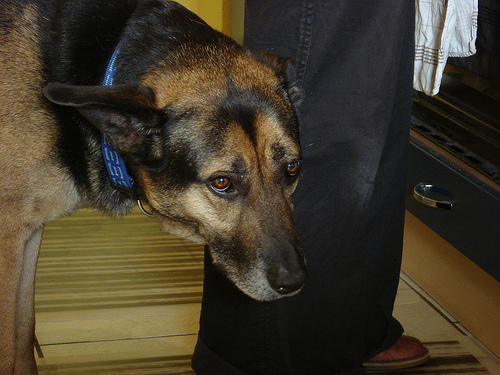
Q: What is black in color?
A: Pant legs of man.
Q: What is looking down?
A: Head of dog.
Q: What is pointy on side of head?
A: Ear of dog.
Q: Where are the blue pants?
A: On a person.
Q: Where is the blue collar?
A: On dog.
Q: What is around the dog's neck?
A: A collar.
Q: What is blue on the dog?
A: Collar.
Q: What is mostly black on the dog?
A: Ear.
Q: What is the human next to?
A: A drawer.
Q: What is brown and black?
A: The dog.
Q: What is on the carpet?
A: Stripes.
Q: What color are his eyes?
A: Brown.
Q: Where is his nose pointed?
A: Down.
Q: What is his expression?
A: Sad.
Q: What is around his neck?
A: Collar.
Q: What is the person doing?
A: Standing.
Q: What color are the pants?
A: Black.